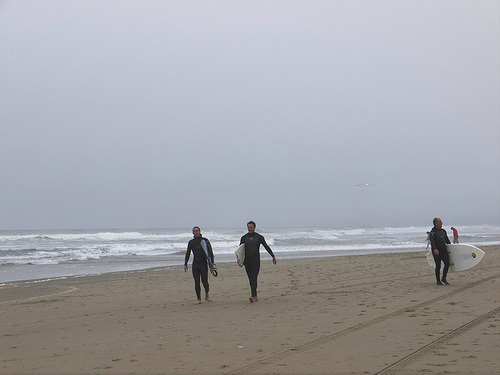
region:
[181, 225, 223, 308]
surfer with a blue surfboard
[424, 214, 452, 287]
bald surfer walking alone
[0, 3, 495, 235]
grey hazy sky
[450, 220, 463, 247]
person with a red shirt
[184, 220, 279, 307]
two surfers walking together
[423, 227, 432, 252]
person in white on the beach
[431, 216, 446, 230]
bald head of a surfer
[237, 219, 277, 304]
The man walking in the middle.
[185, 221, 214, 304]
The man walking on the left.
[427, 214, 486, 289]
The man holding the surfboard on the right.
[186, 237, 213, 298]
The wet suit the man on the left is wearing.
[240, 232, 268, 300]
The wet suit the man in the middle is wearing.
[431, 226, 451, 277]
The wet suit the man on the right is wearing.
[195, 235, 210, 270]
The surfboard the man on the left is carrying.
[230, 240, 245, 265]
The surfboard the man in the middle is carrying.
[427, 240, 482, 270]
The surfboard the man on the right is carrying.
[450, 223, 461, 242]
The person wearing a red jacket in the distance.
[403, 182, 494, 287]
man carrying a surfboard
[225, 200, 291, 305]
man wearing a wetsuit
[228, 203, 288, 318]
wet suit is black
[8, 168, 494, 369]
people walking on a beach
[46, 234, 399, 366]
footprints on the beach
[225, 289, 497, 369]
tire tracks on the beach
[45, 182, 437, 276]
waves crashing in background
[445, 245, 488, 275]
blue emblem on surfboard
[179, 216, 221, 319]
Man walking on the sand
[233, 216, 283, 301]
Man walking on the sand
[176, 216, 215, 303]
Man carrying a surfboard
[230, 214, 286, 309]
Man carrying a surfboard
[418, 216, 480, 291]
Man carrying a surfboard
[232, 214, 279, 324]
Man wearing a black wetsuite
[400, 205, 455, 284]
Man wearing a black wetsuite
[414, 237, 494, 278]
Large white surfboard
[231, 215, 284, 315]
This is a person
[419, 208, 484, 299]
This is a person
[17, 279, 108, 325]
Section of the beach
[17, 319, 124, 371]
Section of the beach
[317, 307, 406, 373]
Section of the beach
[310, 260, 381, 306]
Section of the beach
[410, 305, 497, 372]
Section of the beach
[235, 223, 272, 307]
a man carrying a surf board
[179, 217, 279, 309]
two men walking on a beach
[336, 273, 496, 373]
tire tracks on a beach